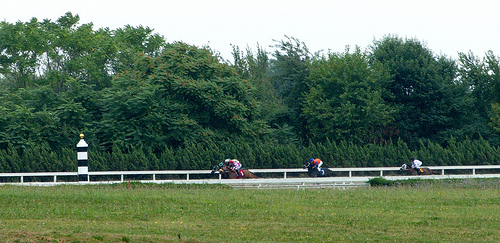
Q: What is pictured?
A: Horse race.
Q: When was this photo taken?
A: Daytime.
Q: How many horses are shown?
A: 3.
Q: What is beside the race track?
A: Trees.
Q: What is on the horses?
A: People.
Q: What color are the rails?
A: White.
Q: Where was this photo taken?
A: At a racetrack.